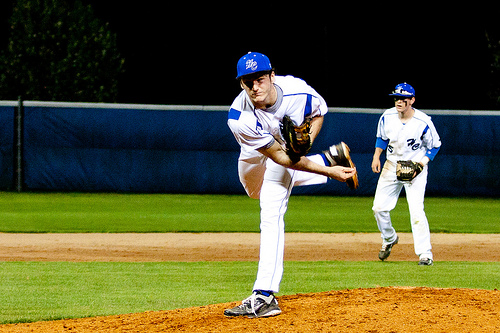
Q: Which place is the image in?
A: It is at the field.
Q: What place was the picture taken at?
A: It was taken at the field.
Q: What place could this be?
A: It is a field.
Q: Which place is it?
A: It is a field.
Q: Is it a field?
A: Yes, it is a field.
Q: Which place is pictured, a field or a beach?
A: It is a field.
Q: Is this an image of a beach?
A: No, the picture is showing a field.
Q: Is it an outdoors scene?
A: Yes, it is outdoors.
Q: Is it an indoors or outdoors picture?
A: It is outdoors.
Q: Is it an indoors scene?
A: No, it is outdoors.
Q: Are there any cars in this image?
A: No, there are no cars.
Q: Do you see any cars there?
A: No, there are no cars.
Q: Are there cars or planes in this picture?
A: No, there are no cars or planes.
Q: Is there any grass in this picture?
A: Yes, there is grass.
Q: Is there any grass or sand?
A: Yes, there is grass.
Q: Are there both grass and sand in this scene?
A: No, there is grass but no sand.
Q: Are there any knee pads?
A: No, there are no knee pads.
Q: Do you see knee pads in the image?
A: No, there are no knee pads.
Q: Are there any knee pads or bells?
A: No, there are no knee pads or bells.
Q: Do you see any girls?
A: No, there are no girls.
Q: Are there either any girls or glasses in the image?
A: No, there are no girls or glasses.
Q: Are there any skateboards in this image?
A: No, there are no skateboards.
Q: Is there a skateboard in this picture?
A: No, there are no skateboards.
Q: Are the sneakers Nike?
A: Yes, the sneakers are nike.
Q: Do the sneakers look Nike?
A: Yes, the sneakers are nike.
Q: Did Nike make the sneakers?
A: Yes, the sneakers were made by nike.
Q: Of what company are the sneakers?
A: The sneakers are nike.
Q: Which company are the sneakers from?
A: The sneakers are from nike.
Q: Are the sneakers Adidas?
A: No, the sneakers are nike.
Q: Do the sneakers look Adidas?
A: No, the sneakers are nike.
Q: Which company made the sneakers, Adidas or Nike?
A: The sneakers were made nike.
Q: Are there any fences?
A: Yes, there is a fence.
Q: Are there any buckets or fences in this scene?
A: Yes, there is a fence.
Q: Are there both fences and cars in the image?
A: No, there is a fence but no cars.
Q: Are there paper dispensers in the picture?
A: No, there are no paper dispensers.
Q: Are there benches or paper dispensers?
A: No, there are no paper dispensers or benches.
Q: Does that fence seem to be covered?
A: Yes, the fence is covered.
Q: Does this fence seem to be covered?
A: Yes, the fence is covered.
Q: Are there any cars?
A: No, there are no cars.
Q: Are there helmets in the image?
A: No, there are no helmets.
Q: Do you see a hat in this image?
A: Yes, there is a hat.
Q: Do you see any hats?
A: Yes, there is a hat.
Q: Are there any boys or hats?
A: Yes, there is a hat.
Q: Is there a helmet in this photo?
A: No, there are no helmets.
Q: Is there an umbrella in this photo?
A: No, there are no umbrellas.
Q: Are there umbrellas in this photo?
A: No, there are no umbrellas.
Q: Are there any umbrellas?
A: No, there are no umbrellas.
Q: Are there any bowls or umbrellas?
A: No, there are no umbrellas or bowls.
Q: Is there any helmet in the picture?
A: No, there are no helmets.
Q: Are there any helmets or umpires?
A: No, there are no helmets or umpires.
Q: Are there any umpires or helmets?
A: No, there are no helmets or umpires.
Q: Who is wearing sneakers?
A: The player is wearing sneakers.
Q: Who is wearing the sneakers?
A: The player is wearing sneakers.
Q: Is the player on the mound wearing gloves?
A: No, the player is wearing sneakers.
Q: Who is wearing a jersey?
A: The player is wearing a jersey.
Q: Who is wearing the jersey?
A: The player is wearing a jersey.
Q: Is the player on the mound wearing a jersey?
A: Yes, the player is wearing a jersey.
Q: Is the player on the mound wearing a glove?
A: No, the player is wearing a jersey.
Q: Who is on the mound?
A: The player is on the mound.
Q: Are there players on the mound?
A: Yes, there is a player on the mound.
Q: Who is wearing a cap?
A: The player is wearing a cap.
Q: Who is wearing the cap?
A: The player is wearing a cap.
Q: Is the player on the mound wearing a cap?
A: Yes, the player is wearing a cap.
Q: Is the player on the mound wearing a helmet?
A: No, the player is wearing a cap.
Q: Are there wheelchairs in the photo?
A: No, there are no wheelchairs.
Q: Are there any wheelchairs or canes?
A: No, there are no wheelchairs or canes.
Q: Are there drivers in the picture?
A: No, there are no drivers.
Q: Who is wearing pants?
A: The player is wearing pants.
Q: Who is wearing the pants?
A: The player is wearing pants.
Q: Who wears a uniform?
A: The player wears a uniform.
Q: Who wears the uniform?
A: The player wears a uniform.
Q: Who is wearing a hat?
A: The player is wearing a hat.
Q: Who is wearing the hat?
A: The player is wearing a hat.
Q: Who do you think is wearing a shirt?
A: The player is wearing a shirt.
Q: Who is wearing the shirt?
A: The player is wearing a shirt.